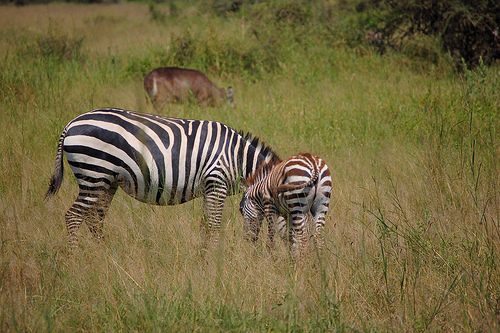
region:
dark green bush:
[353, 3, 495, 71]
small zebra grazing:
[237, 146, 332, 263]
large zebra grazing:
[43, 107, 282, 239]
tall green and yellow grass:
[337, 92, 494, 307]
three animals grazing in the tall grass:
[20, 43, 355, 295]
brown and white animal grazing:
[132, 60, 248, 117]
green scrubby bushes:
[33, 28, 295, 68]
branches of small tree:
[381, 15, 425, 45]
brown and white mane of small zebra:
[243, 160, 286, 180]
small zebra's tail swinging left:
[276, 165, 326, 195]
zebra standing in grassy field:
[238, 151, 334, 263]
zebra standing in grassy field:
[44, 108, 284, 258]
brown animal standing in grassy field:
[141, 65, 237, 117]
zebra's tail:
[41, 123, 71, 199]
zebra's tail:
[273, 163, 318, 195]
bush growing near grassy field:
[366, 0, 498, 70]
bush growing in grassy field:
[131, 25, 288, 79]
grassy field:
[1, 63, 496, 331]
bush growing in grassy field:
[36, 24, 84, 61]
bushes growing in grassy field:
[143, 3, 397, 50]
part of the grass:
[378, 281, 395, 301]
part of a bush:
[401, 260, 427, 286]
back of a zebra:
[316, 183, 326, 188]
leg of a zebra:
[210, 208, 229, 223]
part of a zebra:
[291, 178, 311, 195]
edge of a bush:
[413, 192, 437, 249]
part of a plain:
[209, 278, 231, 300]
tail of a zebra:
[46, 190, 53, 193]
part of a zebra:
[156, 179, 165, 186]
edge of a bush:
[366, 238, 400, 269]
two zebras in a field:
[30, 96, 338, 276]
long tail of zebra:
[35, 121, 75, 197]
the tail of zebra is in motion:
[260, 157, 321, 204]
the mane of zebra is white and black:
[12, 30, 422, 330]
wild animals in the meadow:
[14, 28, 431, 305]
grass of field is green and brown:
[5, 5, 485, 315]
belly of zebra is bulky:
[120, 170, 200, 206]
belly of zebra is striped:
[125, 175, 200, 211]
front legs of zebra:
[192, 195, 227, 245]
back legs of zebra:
[59, 185, 116, 251]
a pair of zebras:
[35, 103, 354, 283]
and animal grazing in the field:
[144, 50, 240, 114]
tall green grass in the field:
[318, 65, 479, 300]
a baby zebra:
[222, 143, 335, 260]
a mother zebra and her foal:
[36, 85, 346, 292]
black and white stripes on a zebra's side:
[103, 128, 193, 186]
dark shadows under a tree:
[372, 14, 496, 78]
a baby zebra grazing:
[234, 145, 336, 279]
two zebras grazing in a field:
[32, 91, 354, 291]